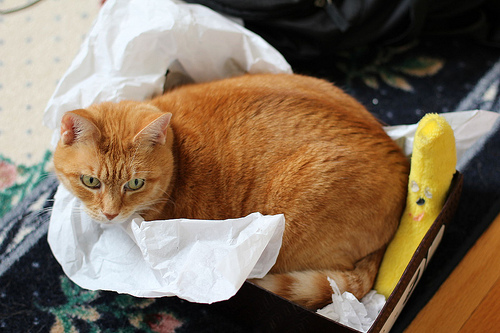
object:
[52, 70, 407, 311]
cat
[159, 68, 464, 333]
box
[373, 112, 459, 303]
toy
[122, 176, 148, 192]
eye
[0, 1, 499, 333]
carpet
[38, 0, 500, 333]
tissue paper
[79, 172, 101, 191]
eye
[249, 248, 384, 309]
tail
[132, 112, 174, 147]
ear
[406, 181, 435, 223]
face